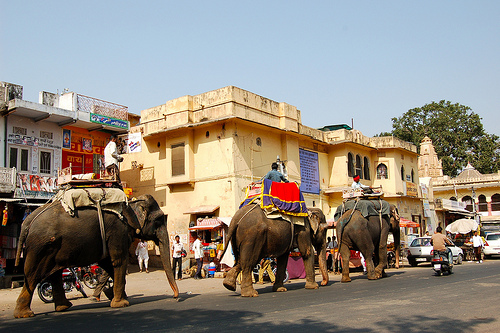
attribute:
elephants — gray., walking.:
[11, 191, 398, 319]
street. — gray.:
[12, 255, 500, 331]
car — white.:
[411, 241, 460, 262]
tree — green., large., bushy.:
[384, 102, 499, 174]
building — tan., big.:
[123, 88, 440, 262]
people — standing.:
[138, 230, 215, 279]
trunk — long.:
[142, 202, 188, 300]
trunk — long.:
[318, 226, 333, 287]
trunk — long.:
[392, 210, 402, 272]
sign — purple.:
[301, 141, 315, 199]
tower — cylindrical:
[419, 132, 447, 180]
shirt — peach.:
[434, 235, 450, 254]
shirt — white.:
[104, 143, 119, 166]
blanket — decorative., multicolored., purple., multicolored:
[266, 183, 311, 221]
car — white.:
[412, 239, 432, 250]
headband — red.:
[352, 176, 362, 180]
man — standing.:
[107, 132, 125, 185]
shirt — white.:
[473, 236, 483, 252]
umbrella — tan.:
[446, 215, 485, 236]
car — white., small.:
[407, 236, 467, 268]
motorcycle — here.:
[40, 262, 100, 298]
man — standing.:
[175, 227, 184, 280]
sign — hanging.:
[15, 183, 63, 200]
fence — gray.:
[56, 156, 114, 182]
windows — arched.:
[443, 184, 499, 213]